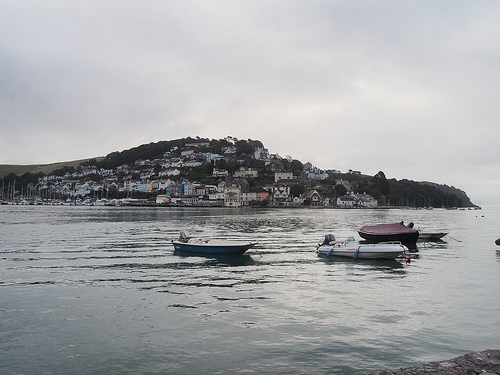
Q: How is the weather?
A: It is cloudy.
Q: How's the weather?
A: It is cloudy.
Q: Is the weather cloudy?
A: Yes, it is cloudy.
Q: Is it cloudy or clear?
A: It is cloudy.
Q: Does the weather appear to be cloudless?
A: No, it is cloudy.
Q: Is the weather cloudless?
A: No, it is cloudy.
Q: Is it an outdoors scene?
A: Yes, it is outdoors.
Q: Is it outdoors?
A: Yes, it is outdoors.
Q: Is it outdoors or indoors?
A: It is outdoors.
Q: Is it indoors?
A: No, it is outdoors.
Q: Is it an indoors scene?
A: No, it is outdoors.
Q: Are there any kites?
A: No, there are no kites.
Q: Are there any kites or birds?
A: No, there are no kites or birds.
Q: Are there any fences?
A: No, there are no fences.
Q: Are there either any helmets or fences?
A: No, there are no fences or helmets.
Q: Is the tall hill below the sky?
A: Yes, the hill is below the sky.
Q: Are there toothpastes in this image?
A: No, there are no toothpastes.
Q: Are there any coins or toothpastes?
A: No, there are no toothpastes or coins.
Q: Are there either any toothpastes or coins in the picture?
A: No, there are no toothpastes or coins.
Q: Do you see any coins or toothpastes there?
A: No, there are no toothpastes or coins.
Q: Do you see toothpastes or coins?
A: No, there are no toothpastes or coins.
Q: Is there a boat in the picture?
A: Yes, there is a boat.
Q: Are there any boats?
A: Yes, there is a boat.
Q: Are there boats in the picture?
A: Yes, there is a boat.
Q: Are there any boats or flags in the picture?
A: Yes, there is a boat.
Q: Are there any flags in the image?
A: No, there are no flags.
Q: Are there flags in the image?
A: No, there are no flags.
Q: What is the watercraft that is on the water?
A: The watercraft is a boat.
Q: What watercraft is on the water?
A: The watercraft is a boat.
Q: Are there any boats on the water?
A: Yes, there is a boat on the water.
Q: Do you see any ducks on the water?
A: No, there is a boat on the water.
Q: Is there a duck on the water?
A: No, there is a boat on the water.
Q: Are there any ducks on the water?
A: No, there is a boat on the water.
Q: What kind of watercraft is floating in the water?
A: The watercraft is a boat.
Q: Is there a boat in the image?
A: Yes, there is a boat.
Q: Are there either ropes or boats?
A: Yes, there is a boat.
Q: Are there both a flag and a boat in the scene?
A: No, there is a boat but no flags.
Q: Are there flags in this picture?
A: No, there are no flags.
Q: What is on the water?
A: The boat is on the water.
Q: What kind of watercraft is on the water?
A: The watercraft is a boat.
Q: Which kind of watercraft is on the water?
A: The watercraft is a boat.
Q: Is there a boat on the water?
A: Yes, there is a boat on the water.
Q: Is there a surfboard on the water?
A: No, there is a boat on the water.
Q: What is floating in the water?
A: The boat is floating in the water.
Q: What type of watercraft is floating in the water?
A: The watercraft is a boat.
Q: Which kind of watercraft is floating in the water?
A: The watercraft is a boat.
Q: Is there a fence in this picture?
A: No, there are no fences.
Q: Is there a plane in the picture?
A: No, there are no airplanes.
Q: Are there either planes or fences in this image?
A: No, there are no planes or fences.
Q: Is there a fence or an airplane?
A: No, there are no airplanes or fences.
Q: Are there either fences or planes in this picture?
A: No, there are no planes or fences.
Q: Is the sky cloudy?
A: Yes, the sky is cloudy.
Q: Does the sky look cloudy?
A: Yes, the sky is cloudy.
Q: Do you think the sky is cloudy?
A: Yes, the sky is cloudy.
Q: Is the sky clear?
A: No, the sky is cloudy.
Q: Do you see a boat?
A: Yes, there is a boat.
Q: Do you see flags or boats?
A: Yes, there is a boat.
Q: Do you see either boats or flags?
A: Yes, there is a boat.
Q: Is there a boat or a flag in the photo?
A: Yes, there is a boat.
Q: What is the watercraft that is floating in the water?
A: The watercraft is a boat.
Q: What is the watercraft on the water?
A: The watercraft is a boat.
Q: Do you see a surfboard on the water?
A: No, there is a boat on the water.